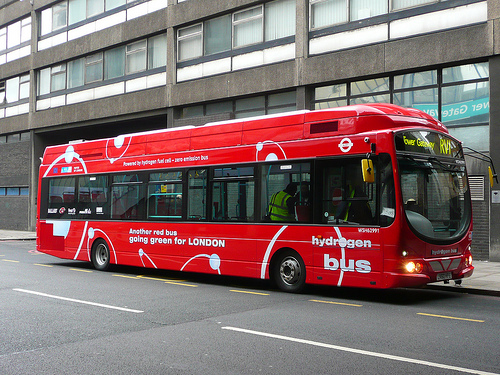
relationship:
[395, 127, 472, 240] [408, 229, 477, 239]
windshield has curved bottom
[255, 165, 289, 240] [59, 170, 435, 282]
man in reflective vest inside of a bus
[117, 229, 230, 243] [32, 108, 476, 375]
marketing slogan on side of bus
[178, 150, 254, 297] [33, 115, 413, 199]
public transit bus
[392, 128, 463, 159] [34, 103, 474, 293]
electric display on front of bus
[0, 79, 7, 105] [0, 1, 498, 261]
window on building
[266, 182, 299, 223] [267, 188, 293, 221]
man wearing vest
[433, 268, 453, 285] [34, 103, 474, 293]
license plate on front of bus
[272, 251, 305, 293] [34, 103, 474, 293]
front tire on right side of bus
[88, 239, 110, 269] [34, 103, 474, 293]
rear tire on right side of bus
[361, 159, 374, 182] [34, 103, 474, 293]
mirror of bus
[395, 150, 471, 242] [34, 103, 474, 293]
windshield of bus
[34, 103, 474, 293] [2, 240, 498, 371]
bus driving on road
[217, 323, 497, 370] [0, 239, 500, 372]
stripe painted on asphalt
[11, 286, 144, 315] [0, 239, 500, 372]
stripe painted on asphalt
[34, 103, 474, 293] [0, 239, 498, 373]
bus parked on street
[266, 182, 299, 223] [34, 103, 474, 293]
man inside bus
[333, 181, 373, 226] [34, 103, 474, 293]
person inside bus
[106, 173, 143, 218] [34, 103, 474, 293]
window on bus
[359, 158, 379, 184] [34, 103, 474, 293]
mirror on bus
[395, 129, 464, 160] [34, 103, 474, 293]
head sign on bus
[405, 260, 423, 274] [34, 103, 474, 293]
bus headlight on front of bus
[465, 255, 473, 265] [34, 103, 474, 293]
bus headlight on front of bus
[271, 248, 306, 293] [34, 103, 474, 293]
front tire underneath bus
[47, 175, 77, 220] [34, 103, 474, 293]
window of bus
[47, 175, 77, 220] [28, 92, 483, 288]
window on bus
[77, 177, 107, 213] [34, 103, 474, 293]
window on bus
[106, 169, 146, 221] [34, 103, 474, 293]
window on bus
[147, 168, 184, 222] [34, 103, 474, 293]
window on bus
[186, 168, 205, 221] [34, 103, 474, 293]
window on bus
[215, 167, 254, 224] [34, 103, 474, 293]
window on bus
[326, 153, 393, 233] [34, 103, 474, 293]
window on bus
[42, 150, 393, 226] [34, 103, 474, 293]
window row on bus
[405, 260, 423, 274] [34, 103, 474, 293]
bus headlight on bus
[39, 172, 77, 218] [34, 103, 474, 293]
window on bus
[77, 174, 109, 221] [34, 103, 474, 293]
window on bus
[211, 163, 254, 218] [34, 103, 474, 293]
window on bus